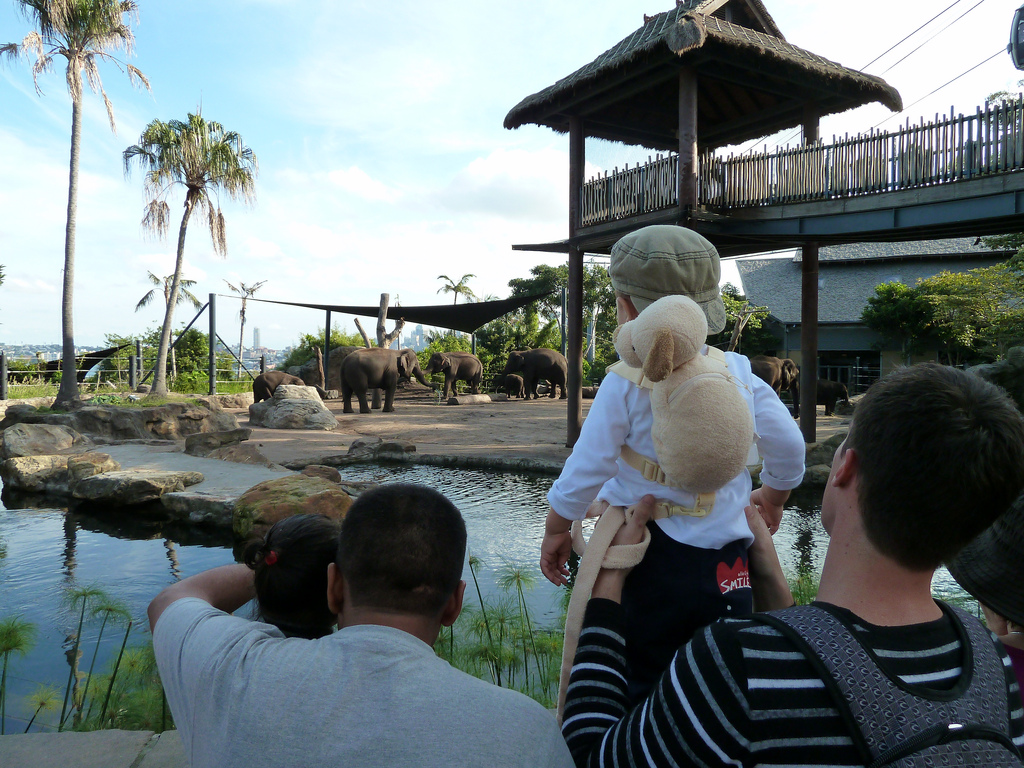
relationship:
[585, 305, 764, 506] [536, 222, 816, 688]
backpack on child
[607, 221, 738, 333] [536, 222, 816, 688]
hat on child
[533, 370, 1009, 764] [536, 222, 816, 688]
man lifting child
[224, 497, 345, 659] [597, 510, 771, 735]
child wearing pants